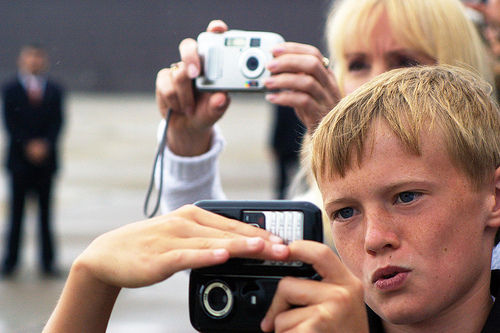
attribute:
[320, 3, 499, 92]
hair — blond, blonde, straight, light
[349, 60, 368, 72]
eye — dark, open, brown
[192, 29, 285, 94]
camera — silver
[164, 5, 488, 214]
woman — behind, preparing, caucasian, blonde, older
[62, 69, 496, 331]
boy — aiming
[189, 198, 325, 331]
cell phone — black, camera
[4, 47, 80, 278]
man — blurry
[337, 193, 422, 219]
eyes — blue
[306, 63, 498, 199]
hair — blonde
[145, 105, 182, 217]
strap — thin, black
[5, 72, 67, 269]
suit — black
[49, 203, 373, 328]
hands — clasped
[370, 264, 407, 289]
mouth — open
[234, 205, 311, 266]
cellphone — silver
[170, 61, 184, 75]
ring — large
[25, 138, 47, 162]
hands — together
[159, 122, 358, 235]
shirt — white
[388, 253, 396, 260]
mole — black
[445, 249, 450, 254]
mole — black